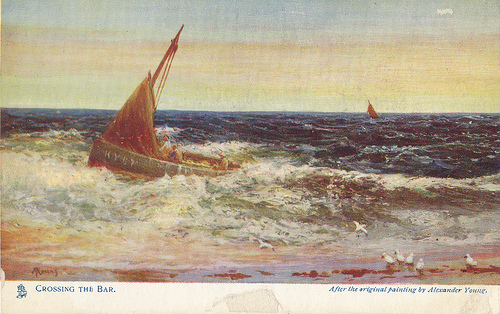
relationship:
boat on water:
[87, 24, 249, 190] [1, 105, 499, 288]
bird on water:
[351, 217, 370, 237] [1, 105, 499, 288]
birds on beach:
[381, 245, 479, 275] [10, 239, 497, 309]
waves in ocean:
[14, 125, 498, 244] [5, 106, 498, 281]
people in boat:
[158, 131, 185, 165] [87, 24, 249, 190]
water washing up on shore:
[96, 186, 317, 269] [1, 231, 485, 281]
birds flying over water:
[256, 218, 367, 249] [247, 126, 496, 219]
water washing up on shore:
[96, 186, 317, 269] [14, 231, 484, 288]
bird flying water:
[351, 217, 370, 237] [0, 110, 498, 260]